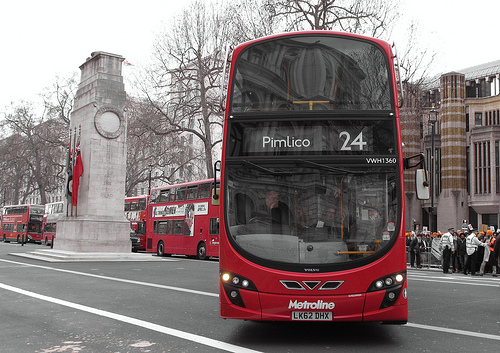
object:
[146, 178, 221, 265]
bus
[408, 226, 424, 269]
people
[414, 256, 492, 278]
sidewalk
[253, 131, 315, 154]
letters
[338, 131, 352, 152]
numbers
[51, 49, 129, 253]
buildings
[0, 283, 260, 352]
lines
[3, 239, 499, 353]
street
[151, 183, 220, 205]
upper deck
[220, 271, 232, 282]
headlights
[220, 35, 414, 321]
bus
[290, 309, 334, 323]
license plate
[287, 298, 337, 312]
metroline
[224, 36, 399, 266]
windshield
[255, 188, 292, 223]
bus driver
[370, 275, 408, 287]
headlight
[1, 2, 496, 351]
city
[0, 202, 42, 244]
bus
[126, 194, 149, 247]
bus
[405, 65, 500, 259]
building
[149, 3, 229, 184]
tree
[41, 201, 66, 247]
passenger bus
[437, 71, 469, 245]
pillar